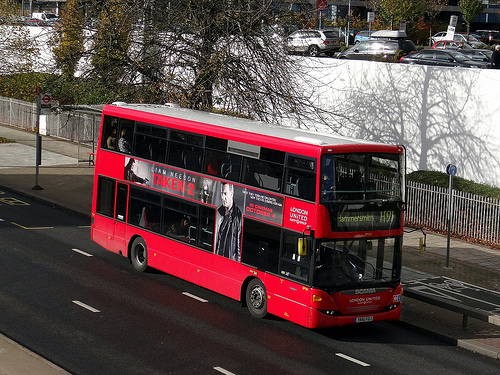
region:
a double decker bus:
[78, 91, 386, 330]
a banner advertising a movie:
[125, 157, 218, 202]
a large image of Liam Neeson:
[218, 180, 239, 252]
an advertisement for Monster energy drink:
[331, 211, 396, 228]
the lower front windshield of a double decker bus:
[319, 236, 405, 304]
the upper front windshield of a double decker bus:
[327, 154, 399, 203]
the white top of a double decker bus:
[124, 97, 353, 155]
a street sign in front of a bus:
[441, 165, 459, 270]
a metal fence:
[459, 191, 498, 252]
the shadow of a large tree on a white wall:
[362, 59, 495, 161]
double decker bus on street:
[63, 100, 423, 306]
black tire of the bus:
[225, 260, 292, 330]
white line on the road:
[62, 294, 120, 332]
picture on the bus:
[206, 173, 248, 252]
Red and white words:
[133, 158, 209, 209]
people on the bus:
[80, 96, 146, 171]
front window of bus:
[304, 134, 414, 227]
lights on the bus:
[310, 288, 407, 339]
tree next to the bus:
[391, 93, 478, 145]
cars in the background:
[378, 23, 462, 86]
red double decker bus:
[83, 92, 410, 330]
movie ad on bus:
[120, 151, 285, 261]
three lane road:
[1, 277, 497, 367]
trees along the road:
[3, 0, 498, 144]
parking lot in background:
[3, 5, 498, 69]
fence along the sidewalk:
[409, 183, 499, 290]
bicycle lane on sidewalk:
[438, 270, 499, 308]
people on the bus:
[95, 105, 140, 160]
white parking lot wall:
[26, 27, 498, 157]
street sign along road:
[28, 86, 54, 209]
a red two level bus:
[0, 95, 430, 345]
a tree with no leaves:
[181, 22, 285, 100]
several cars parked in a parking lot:
[291, 25, 480, 64]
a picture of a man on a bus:
[206, 175, 248, 280]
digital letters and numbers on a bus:
[325, 207, 401, 237]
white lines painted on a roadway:
[46, 243, 106, 327]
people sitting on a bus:
[88, 107, 140, 165]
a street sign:
[16, 77, 58, 197]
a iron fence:
[423, 190, 487, 226]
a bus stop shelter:
[70, 95, 98, 169]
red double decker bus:
[87, 94, 406, 328]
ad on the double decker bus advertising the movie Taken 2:
[112, 152, 287, 265]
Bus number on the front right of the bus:
[377, 207, 399, 227]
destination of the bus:
[336, 208, 378, 228]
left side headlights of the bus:
[323, 307, 336, 316]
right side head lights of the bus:
[387, 302, 399, 311]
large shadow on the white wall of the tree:
[353, 59, 496, 181]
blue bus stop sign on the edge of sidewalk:
[444, 162, 457, 268]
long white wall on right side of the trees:
[0, 22, 499, 187]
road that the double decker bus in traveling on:
[10, 197, 177, 349]